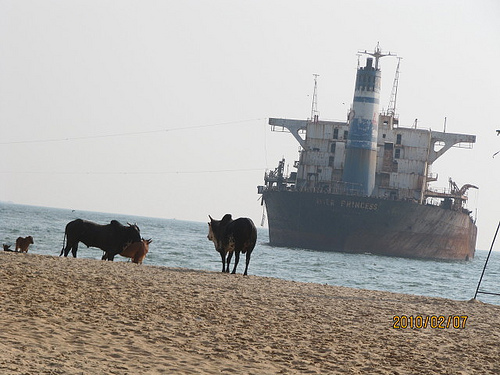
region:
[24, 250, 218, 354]
Heavily trampled sand at the shore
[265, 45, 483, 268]
A large metal ship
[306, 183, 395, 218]
The ship's name painted on the sie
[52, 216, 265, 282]
Cattle at the beach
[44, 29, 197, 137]
A gloomy grey sky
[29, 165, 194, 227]
The sky and water meet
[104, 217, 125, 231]
The hump on a bull's back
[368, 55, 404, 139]
An antenna on top of a ship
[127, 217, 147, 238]
Two horns on a bulls head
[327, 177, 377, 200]
Railing on a ship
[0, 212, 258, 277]
Four animals on the ocean shore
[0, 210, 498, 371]
Animals standing near the ocean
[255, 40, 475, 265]
Ship on the ocean water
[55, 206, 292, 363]
Cows standing on the shore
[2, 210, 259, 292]
Four animals on the sea shore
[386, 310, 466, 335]
Date when picture was taken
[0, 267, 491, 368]
Sand on the sea shore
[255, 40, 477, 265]
Rig on the sea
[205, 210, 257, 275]
A bull looking at other cows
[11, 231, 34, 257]
Dog walking behind the cows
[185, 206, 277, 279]
large animal standing on the beach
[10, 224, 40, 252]
large animal standing on the beach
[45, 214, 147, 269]
large animal standing on the beach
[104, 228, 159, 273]
large animal standing on the beach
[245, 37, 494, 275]
large ship in the water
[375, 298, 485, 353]
time stamp of the photo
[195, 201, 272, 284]
brown and white animal on the beach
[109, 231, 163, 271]
brown animal on the beach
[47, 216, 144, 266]
dark brown animal on the beach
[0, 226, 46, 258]
brown animal on the beach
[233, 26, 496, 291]
the ship is big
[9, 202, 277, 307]
animals are standing on the beach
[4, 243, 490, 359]
the sand is brown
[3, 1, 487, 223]
the sky is gray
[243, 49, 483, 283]
the ship is brown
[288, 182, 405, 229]
the ship says princess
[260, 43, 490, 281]
the ship looks rusty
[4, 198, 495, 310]
the water is calm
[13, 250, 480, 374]
footprints in the sand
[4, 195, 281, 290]
a group of animals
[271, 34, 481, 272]
a big ship in the sea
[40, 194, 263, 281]
a couple of cows on the sand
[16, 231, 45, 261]
cow by the water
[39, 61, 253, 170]
a hazy sky during the day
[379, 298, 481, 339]
the date that the photo was taken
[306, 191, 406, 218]
the princess ship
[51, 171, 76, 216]
something by the ocean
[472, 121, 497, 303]
a pole on the sand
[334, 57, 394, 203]
a pipe in the boat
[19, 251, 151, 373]
the sand on the beach